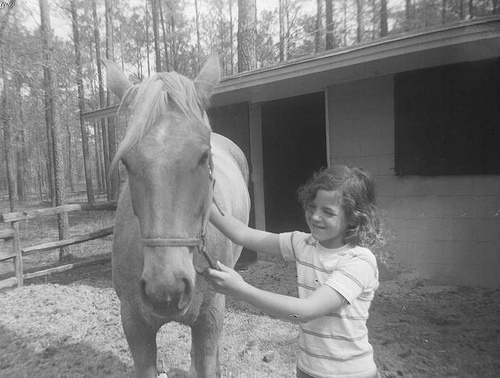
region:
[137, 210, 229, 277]
halter on horse's head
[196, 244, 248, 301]
child is holding onto halter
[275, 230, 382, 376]
child is wearing striped shirt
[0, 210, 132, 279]
wooden rail fence beside stall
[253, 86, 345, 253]
open door of horse stall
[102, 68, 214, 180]
long mane on horse's head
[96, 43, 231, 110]
horse's ears are up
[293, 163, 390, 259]
child has curly hair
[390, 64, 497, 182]
dark board over window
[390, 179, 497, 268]
shingle siding on barn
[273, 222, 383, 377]
the shirt is striped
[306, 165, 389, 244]
the hair is brown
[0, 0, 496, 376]
the photo is black and white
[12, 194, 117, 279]
the fence is wooden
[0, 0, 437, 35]
trees are in the background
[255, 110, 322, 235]
the door is open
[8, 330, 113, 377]
shadow is on the ground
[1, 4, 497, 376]
the scene is outdoors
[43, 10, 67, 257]
the tree trunk is narrow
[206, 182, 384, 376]
the boy is touching the horse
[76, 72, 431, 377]
a girl and a horse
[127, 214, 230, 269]
a strap across horses mouth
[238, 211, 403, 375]
a white shirt with stripes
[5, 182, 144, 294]
a wooden fence for horse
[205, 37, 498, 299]
a building to house the horse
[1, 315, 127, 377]
shadow on ground from horse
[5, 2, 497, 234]
many tall trees behind horse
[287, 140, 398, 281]
long curly hair on girl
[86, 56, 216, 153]
long hair on horses head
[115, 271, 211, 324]
dark nose of horse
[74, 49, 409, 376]
young kid touching a horse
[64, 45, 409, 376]
young kid next to a horse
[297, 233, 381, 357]
white striped shirt on kid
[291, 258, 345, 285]
stripes on front of shirt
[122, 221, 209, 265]
rope around face of horse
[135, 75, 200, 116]
top part of mane of horse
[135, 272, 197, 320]
black snout on horse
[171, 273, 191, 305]
large black nostril of horse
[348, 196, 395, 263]
long hair of kid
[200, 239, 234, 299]
hand grabbing a rope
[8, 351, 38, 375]
Small imprints in the dirt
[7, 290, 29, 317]
Small imprints in the dirt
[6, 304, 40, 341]
Small imprints in the dirt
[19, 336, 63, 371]
Small imprints in the dirt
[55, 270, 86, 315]
Small imprints in the dirt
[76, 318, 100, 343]
Small imprints in the dirt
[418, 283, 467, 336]
Small imprints in the dirt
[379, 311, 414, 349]
Small imprints in the dirt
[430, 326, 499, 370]
Small imprints in the dirt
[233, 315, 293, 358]
Small imprints in the dirt